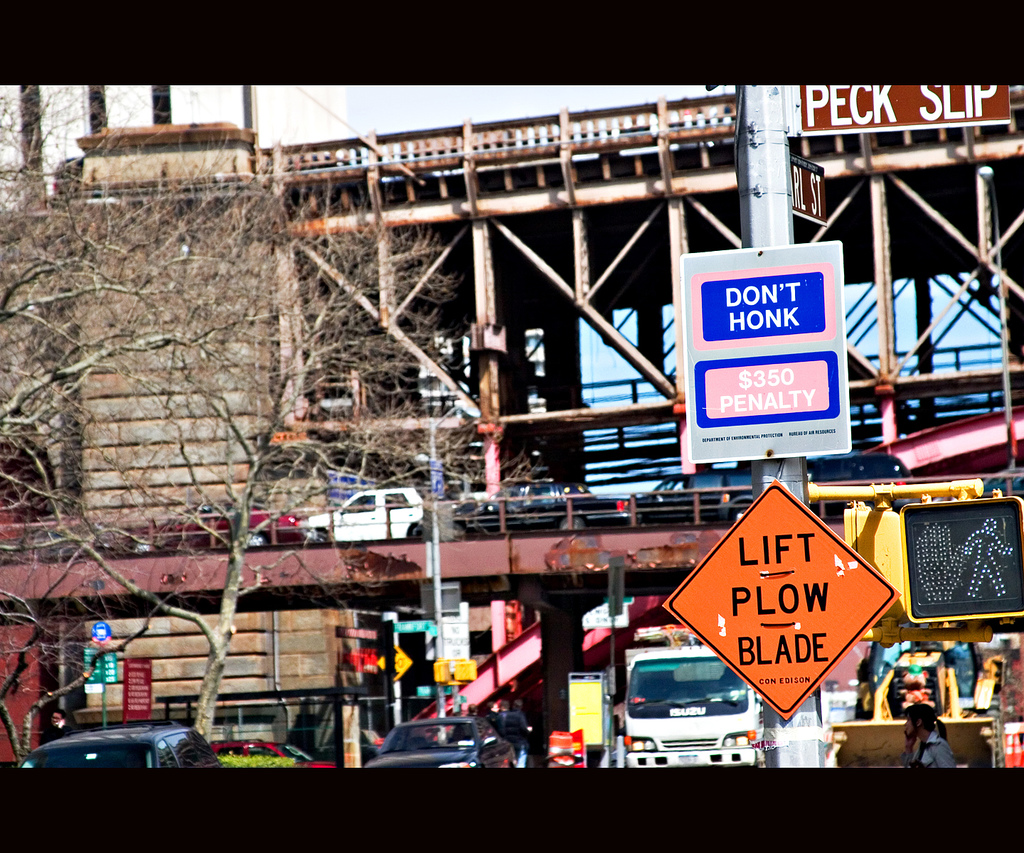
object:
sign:
[662, 479, 901, 722]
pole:
[736, 84, 816, 773]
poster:
[681, 241, 854, 465]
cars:
[304, 486, 433, 544]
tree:
[0, 81, 555, 761]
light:
[433, 659, 479, 687]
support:
[77, 182, 305, 542]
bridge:
[0, 84, 1022, 240]